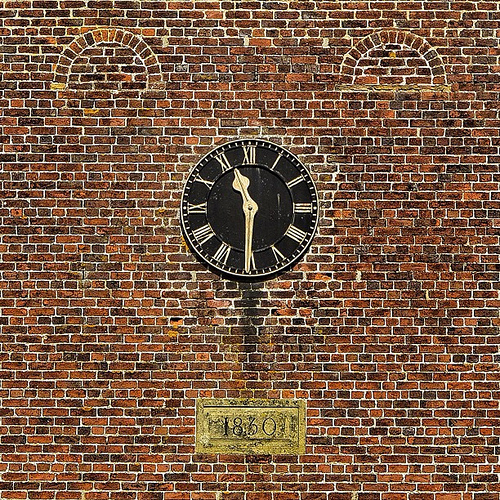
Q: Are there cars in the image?
A: No, there are no cars.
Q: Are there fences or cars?
A: No, there are no cars or fences.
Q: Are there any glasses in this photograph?
A: No, there are no glasses.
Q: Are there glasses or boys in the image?
A: No, there are no glasses or boys.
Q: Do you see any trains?
A: No, there are no trains.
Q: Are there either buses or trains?
A: No, there are no trains or buses.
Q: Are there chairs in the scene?
A: No, there are no chairs.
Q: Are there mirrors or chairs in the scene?
A: No, there are no chairs or mirrors.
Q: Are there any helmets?
A: No, there are no helmets.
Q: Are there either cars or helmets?
A: No, there are no helmets or cars.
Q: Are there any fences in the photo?
A: No, there are no fences.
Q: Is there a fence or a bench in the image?
A: No, there are no fences or benches.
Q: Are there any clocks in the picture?
A: Yes, there is a clock.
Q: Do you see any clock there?
A: Yes, there is a clock.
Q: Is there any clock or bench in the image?
A: Yes, there is a clock.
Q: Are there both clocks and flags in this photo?
A: No, there is a clock but no flags.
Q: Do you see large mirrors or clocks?
A: Yes, there is a large clock.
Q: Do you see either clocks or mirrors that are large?
A: Yes, the clock is large.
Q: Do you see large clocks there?
A: Yes, there is a large clock.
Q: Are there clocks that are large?
A: Yes, there is a clock that is large.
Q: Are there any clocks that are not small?
A: Yes, there is a large clock.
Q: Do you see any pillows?
A: No, there are no pillows.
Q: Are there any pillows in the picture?
A: No, there are no pillows.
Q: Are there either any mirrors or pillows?
A: No, there are no pillows or mirrors.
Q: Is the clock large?
A: Yes, the clock is large.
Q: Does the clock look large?
A: Yes, the clock is large.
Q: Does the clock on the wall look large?
A: Yes, the clock is large.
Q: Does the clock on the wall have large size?
A: Yes, the clock is large.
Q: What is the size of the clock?
A: The clock is large.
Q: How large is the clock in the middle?
A: The clock is large.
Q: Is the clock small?
A: No, the clock is large.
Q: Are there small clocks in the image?
A: No, there is a clock but it is large.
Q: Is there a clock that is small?
A: No, there is a clock but it is large.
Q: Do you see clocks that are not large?
A: No, there is a clock but it is large.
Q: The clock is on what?
A: The clock is on the wall.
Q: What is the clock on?
A: The clock is on the wall.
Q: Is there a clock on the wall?
A: Yes, there is a clock on the wall.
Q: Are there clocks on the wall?
A: Yes, there is a clock on the wall.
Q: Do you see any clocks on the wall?
A: Yes, there is a clock on the wall.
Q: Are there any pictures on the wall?
A: No, there is a clock on the wall.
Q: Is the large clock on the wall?
A: Yes, the clock is on the wall.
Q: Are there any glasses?
A: No, there are no glasses.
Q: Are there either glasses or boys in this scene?
A: No, there are no glasses or boys.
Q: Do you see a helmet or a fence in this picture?
A: No, there are no helmets or fences.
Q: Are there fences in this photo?
A: No, there are no fences.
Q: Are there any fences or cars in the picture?
A: No, there are no fences or cars.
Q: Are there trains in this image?
A: No, there are no trains.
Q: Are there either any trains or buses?
A: No, there are no trains or buses.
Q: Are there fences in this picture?
A: No, there are no fences.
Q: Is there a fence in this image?
A: No, there are no fences.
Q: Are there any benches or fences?
A: No, there are no fences or benches.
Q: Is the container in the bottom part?
A: Yes, the container is in the bottom of the image.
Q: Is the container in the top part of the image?
A: No, the container is in the bottom of the image.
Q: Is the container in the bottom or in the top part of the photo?
A: The container is in the bottom of the image.